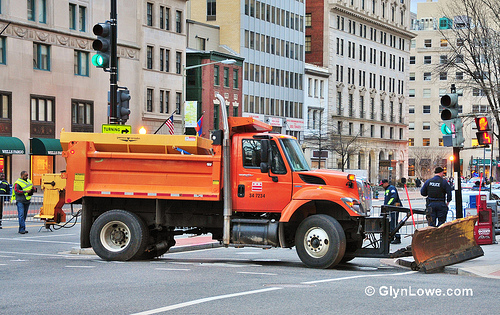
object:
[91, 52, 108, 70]
green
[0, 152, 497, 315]
street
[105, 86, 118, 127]
light post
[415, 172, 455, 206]
candy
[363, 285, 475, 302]
letters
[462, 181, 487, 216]
newspaper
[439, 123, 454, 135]
light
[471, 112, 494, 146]
stop hand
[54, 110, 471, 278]
orange truck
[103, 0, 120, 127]
pole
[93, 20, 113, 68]
traffic light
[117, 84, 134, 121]
traffic light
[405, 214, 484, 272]
snow plow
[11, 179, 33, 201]
vest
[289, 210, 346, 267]
wheel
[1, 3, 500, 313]
city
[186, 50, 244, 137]
building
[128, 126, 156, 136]
sign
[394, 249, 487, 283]
curb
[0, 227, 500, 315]
ground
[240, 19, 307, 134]
building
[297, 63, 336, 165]
building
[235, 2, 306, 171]
building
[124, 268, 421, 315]
lines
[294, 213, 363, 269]
wheel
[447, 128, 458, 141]
hand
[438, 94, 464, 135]
traffic light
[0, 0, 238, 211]
buildings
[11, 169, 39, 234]
construction worker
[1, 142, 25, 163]
awning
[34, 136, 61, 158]
awning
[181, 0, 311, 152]
building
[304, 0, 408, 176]
building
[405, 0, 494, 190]
building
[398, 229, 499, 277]
sidewalk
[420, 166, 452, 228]
man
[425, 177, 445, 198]
shirt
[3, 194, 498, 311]
road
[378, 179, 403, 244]
police officer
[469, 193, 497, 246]
newspaper dispensor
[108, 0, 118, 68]
light post